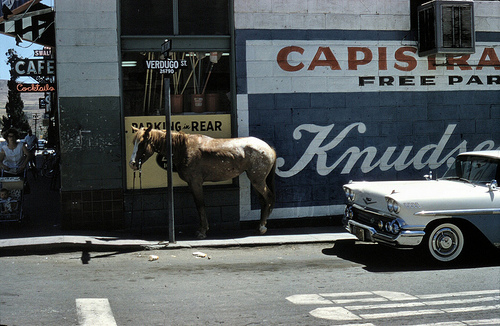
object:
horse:
[128, 125, 277, 239]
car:
[340, 146, 499, 267]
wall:
[55, 0, 127, 230]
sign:
[142, 38, 190, 243]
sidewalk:
[35, 222, 75, 248]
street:
[0, 265, 99, 298]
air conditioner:
[413, 0, 476, 57]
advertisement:
[232, 38, 499, 230]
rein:
[130, 158, 143, 237]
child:
[0, 187, 16, 222]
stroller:
[0, 166, 30, 231]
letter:
[274, 121, 499, 177]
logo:
[360, 196, 378, 206]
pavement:
[284, 276, 499, 325]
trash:
[145, 254, 161, 263]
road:
[144, 277, 258, 325]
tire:
[422, 220, 470, 266]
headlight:
[386, 197, 401, 214]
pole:
[163, 77, 175, 243]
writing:
[356, 73, 499, 87]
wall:
[229, 0, 499, 227]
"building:
[0, 0, 499, 231]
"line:
[73, 296, 118, 325]